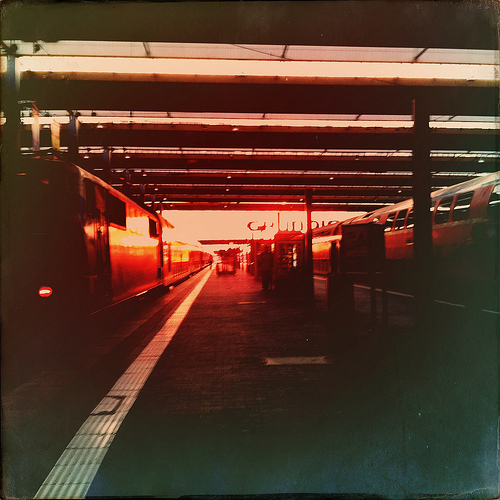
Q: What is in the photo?
A: Train.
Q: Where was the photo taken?
A: Underground.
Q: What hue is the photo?
A: Red.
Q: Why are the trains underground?
A: Subway.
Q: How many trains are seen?
A: Two.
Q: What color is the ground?
A: Black.